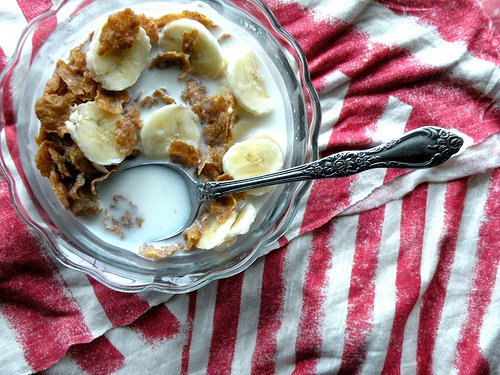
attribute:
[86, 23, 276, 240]
cereal — brown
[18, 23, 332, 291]
bowl — glass, clear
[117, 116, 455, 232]
spoon — silver, metallic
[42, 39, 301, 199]
bananas — sliced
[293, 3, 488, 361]
towel — striped, red, white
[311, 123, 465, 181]
handle — carved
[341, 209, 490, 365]
stripes — red